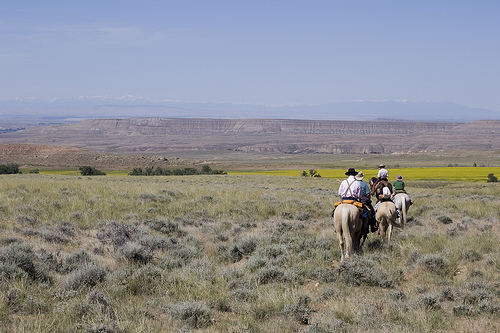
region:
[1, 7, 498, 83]
the clear blue sky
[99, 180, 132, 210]
green grass on ground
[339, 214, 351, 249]
tail on the white horse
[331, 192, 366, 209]
saddle on the horse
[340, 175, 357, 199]
suspenders on back of man's shirt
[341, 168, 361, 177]
black hat on man's head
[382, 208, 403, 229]
tail on beige horse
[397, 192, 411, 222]
tail on the white horse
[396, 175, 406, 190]
person riding the white horse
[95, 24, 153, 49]
clouds in the sky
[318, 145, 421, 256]
group of men riding horses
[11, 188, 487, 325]
plain of grass on land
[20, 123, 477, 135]
terrain in the distance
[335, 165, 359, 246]
man on a horse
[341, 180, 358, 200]
shirt on a man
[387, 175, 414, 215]
man on a horse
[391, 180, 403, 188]
shirt on a man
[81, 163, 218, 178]
trees in the distance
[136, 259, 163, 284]
thick clump of grass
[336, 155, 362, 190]
the head of a man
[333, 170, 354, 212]
the arm of a man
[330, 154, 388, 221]
the body of a man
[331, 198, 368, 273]
the tail on a horse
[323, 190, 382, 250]
the back of a horse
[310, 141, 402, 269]
a man on a horse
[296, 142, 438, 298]
a horse in a field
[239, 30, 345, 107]
a clear blue sky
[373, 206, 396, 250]
horse on the trail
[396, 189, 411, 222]
horse on the trail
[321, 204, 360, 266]
horse on the trail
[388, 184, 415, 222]
horse on the trail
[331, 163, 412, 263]
the people on the horses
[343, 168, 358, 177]
the hat is black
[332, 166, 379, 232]
the person wearing the hat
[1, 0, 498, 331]
the blue sky above the grass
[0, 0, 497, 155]
the blue sky above the mountain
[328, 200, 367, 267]
rear end of white horse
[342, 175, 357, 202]
suspenders on man's back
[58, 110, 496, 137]
top edge of distant mesa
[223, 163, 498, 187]
field of flowers near mesa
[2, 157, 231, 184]
row of trees near field of flowers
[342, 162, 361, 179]
black hat on person's head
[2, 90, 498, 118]
distant snowy mountain peaks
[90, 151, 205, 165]
brown rocks beyond trees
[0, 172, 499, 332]
field of low brush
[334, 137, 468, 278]
people in the background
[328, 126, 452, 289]
people riding horses in the background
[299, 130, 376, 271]
a man wearing white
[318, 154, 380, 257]
a man with a black hat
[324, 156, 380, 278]
a tan horse tail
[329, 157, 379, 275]
a brown horse in the background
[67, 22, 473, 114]
clear blue sky in the background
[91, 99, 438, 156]
small rocky hills in the background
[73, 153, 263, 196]
bushes in the background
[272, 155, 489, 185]
bright green grass in the background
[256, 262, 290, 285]
A shrub in the ground.